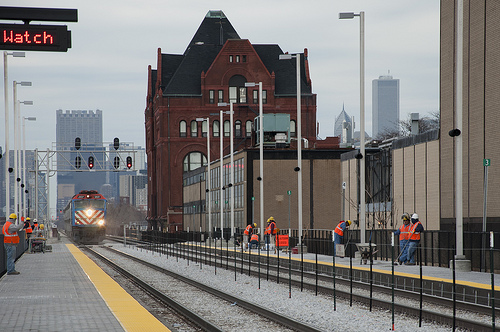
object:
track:
[91, 249, 315, 330]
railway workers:
[242, 220, 255, 248]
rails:
[148, 262, 500, 332]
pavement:
[13, 281, 73, 328]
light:
[81, 206, 98, 218]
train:
[62, 190, 109, 245]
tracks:
[108, 245, 205, 312]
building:
[144, 10, 318, 233]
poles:
[129, 233, 496, 331]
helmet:
[9, 213, 18, 219]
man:
[1, 213, 25, 275]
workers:
[391, 213, 424, 266]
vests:
[244, 224, 253, 235]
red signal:
[88, 163, 95, 168]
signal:
[127, 156, 133, 169]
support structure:
[29, 144, 137, 172]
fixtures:
[339, 12, 355, 19]